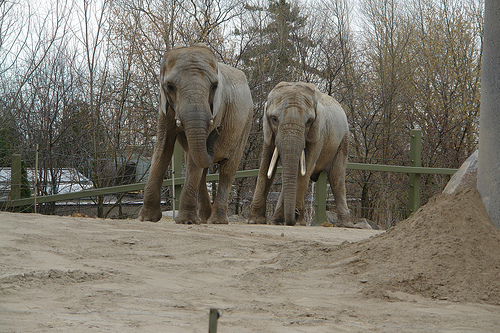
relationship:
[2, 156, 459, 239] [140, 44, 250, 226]
fence behind elephant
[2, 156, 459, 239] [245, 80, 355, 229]
fence behind elephant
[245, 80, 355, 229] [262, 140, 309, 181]
elephant has tusks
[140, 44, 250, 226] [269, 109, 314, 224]
elephant has trunk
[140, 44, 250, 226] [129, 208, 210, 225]
elephant has toe nails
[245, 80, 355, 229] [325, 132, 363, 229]
elephant has leg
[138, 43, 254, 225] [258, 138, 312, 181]
elephant has tusks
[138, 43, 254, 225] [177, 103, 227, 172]
elephant has elephant trunk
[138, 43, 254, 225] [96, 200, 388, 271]
elephant coming up an incline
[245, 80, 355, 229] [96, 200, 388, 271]
elephant coming up an incline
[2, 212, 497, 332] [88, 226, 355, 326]
sand on trail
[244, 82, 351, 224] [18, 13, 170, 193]
elephant standing outside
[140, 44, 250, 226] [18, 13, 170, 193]
elephant standing outside